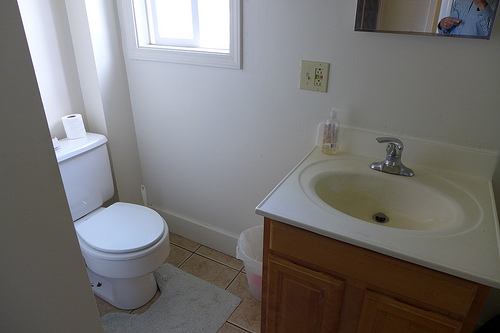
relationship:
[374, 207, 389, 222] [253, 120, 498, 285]
stopper in sink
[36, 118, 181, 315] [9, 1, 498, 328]
toilet in bathroom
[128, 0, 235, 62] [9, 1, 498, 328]
window in bathroom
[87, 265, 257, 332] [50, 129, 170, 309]
mat in front of toilet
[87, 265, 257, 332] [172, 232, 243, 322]
mat on floor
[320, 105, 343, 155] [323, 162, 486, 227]
soap on sink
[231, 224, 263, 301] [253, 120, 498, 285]
basket near sink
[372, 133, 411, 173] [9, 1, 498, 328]
faucet in bathroom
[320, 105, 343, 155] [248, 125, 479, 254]
soap on sink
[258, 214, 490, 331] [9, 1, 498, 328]
cabinet in bathroom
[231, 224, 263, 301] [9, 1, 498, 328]
basket in bathroom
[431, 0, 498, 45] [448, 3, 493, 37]
person has blue shirt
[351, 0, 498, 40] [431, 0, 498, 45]
bathroom mirror reflecting person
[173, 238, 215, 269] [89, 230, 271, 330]
beige tile on floor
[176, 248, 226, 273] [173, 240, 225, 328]
beige tile on floor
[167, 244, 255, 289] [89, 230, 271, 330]
tile on floor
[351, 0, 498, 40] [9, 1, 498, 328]
bathroom mirror in bathroom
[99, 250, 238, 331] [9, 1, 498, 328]
rug inside bathroom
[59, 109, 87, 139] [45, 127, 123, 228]
tissue sitting on toilet tank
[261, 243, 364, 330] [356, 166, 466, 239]
cabinets underneath sink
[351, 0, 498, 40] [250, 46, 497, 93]
bathroom mirror hanging on wall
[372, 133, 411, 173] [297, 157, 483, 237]
faucet above sink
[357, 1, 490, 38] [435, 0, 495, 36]
reflection of person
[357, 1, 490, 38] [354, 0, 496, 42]
reflection in mirror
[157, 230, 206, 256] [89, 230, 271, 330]
tile on floor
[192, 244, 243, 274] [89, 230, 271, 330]
tile on floor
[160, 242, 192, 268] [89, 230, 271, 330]
tile on floor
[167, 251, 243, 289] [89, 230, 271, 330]
tile on floor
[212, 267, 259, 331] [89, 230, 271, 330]
tile on floor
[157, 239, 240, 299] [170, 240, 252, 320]
tile on floor